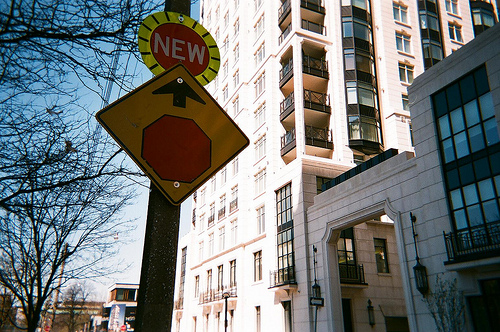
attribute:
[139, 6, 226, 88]
sign — red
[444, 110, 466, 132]
window — rectangular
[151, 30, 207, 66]
lettering — white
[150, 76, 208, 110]
arrow — black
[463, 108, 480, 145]
window — rectangular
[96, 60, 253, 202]
sign — diamond shaped, yellow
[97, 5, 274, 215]
sign — small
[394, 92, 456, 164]
window — rectangular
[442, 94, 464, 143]
window — rectangular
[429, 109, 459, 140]
window — rectangular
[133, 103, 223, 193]
sign — red, yellow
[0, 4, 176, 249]
sky — blue, clear